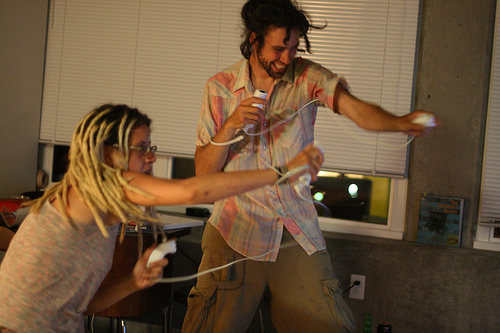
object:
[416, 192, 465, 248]
book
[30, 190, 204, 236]
ledge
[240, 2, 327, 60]
hair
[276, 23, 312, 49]
part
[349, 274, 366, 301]
socket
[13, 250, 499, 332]
wall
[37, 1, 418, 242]
window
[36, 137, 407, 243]
bottom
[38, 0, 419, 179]
blinds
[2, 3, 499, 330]
room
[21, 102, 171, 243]
dreadlocks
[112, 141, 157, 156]
glasses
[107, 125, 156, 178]
face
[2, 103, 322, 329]
player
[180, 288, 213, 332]
pocket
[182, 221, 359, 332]
pants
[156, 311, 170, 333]
legs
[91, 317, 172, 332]
bottom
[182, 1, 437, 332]
man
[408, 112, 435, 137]
wii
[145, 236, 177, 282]
wii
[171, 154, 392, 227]
pane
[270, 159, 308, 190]
strap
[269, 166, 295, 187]
wrist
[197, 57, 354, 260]
shirt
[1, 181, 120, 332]
top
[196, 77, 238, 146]
sleeve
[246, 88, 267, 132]
controller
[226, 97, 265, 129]
hand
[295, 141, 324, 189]
controller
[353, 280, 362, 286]
plug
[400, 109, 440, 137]
hand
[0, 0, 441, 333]
couple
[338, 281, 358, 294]
cable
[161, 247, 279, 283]
wire